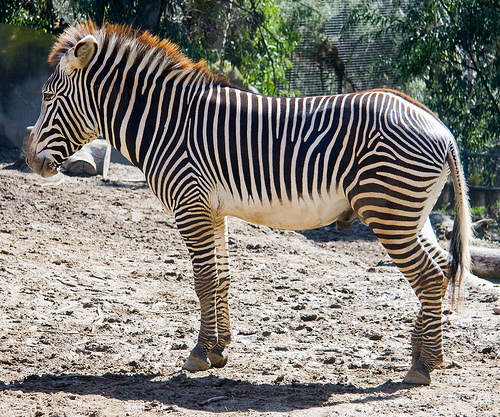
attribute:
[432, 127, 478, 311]
zebra tail — black and white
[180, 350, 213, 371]
zebra's feet — black, white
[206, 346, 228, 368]
zebra's feet — black, white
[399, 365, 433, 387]
zebra's feet — black, white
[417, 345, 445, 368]
zebra's feet — black, white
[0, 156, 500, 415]
ground — muddy, brown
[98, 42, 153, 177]
neck — black and white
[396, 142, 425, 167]
wall — dirty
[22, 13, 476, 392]
zebra — black, white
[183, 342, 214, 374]
hoof — dirty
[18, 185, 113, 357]
ground — brown, muddy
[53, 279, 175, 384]
ground — muddy, grey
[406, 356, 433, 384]
hoof — dirty, black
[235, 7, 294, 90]
leaves — green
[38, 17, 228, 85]
mane — spiky, black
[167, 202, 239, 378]
legs — striped, black and white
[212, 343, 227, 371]
hoof — black